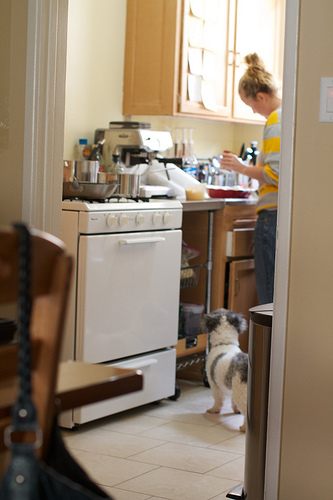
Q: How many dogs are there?
A: One.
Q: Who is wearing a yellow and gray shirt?
A: The woman.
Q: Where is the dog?
A: Standing on the kitchen floor.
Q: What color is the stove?
A: White.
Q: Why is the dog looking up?
A: He is looking at the woman's food.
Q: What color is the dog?
A: Gray and white.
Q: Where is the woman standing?
A: In a kitchen.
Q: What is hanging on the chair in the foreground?
A: A purse.